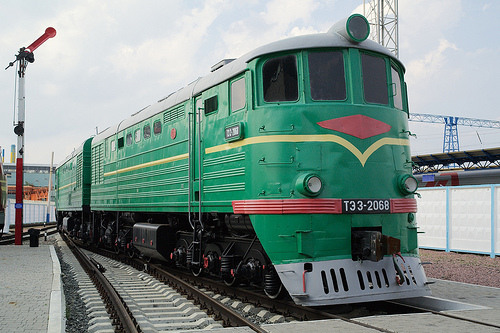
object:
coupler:
[351, 230, 401, 265]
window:
[262, 54, 300, 103]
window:
[360, 50, 390, 105]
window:
[389, 65, 402, 110]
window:
[135, 129, 140, 141]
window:
[308, 50, 347, 102]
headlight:
[296, 173, 325, 196]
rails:
[187, 108, 204, 232]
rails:
[54, 228, 500, 333]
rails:
[0, 224, 56, 244]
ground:
[419, 250, 499, 285]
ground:
[0, 257, 74, 333]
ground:
[232, 297, 283, 322]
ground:
[22, 225, 51, 236]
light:
[345, 13, 369, 41]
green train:
[54, 14, 435, 308]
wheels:
[170, 238, 287, 300]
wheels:
[70, 224, 136, 258]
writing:
[344, 201, 390, 212]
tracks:
[53, 239, 300, 332]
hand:
[188, 108, 205, 232]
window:
[204, 95, 219, 115]